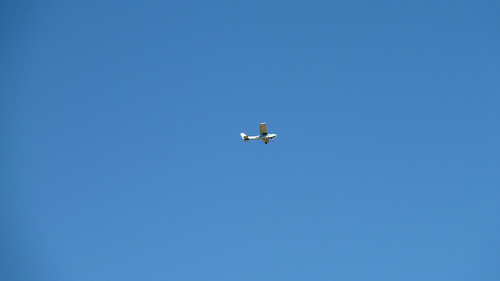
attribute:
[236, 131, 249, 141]
tail — end , blunt 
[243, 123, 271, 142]
body — oval 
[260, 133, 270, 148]
wheel — tiny 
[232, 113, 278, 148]
plane — horizontal 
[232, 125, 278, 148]
airplane — small 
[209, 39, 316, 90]
blue sky — blue 